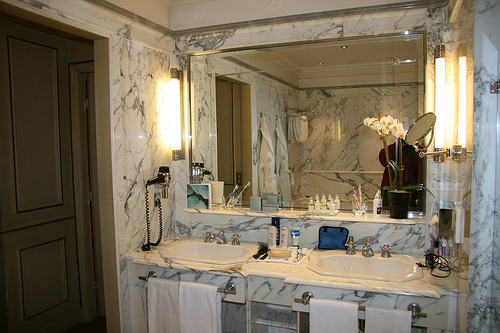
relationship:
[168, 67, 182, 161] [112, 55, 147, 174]
light on a wall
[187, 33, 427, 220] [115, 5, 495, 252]
mirror on wall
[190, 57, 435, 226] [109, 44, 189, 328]
mirror mounted to wall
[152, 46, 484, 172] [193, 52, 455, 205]
lights on both sides of mirror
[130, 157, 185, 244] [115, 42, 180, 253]
hairdryer on wall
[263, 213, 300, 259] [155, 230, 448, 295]
toiletries on counter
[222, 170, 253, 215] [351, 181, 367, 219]
glass in a glass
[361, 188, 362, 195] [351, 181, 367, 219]
glass in a glass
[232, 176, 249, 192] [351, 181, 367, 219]
toothbrush in a glass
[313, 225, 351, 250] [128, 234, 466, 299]
blue bag on counter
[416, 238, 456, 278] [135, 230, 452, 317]
blackcord on counter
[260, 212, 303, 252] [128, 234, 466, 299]
containers on counter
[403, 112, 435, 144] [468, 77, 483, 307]
mirror attached to wall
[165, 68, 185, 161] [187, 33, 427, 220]
light on mirror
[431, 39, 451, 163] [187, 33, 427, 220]
light on mirror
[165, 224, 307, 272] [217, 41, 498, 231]
sink under mirror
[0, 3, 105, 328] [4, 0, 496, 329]
doorway in bathroom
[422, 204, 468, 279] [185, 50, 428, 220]
items near mirror